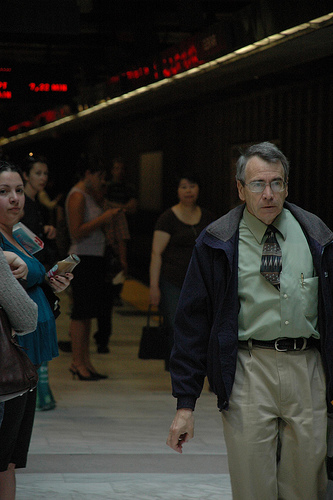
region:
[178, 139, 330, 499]
Man wearing a green button down shirt with a colorful tie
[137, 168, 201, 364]
Woman with black hair walking and carrying a black purse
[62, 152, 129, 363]
Woman standing still and looking at her cell phone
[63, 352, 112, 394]
Black high heel shoes being worn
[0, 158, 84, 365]
Woman wearing a blue shirt holding a bottle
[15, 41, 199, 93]
Red lights in the sky line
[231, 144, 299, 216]
Man with gray hair and wearing glasses without rims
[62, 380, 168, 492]
Light colored stone floor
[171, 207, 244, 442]
Blue jacket with gray pads at the top for warmth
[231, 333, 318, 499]
Khaki pants being worn with a black belt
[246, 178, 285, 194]
Eyeglasses in the photo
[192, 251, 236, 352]
A blue jacket in the photo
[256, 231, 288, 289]
A tie in the photo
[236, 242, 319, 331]
A light green shirt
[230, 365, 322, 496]
A gray trouser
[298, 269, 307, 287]
A pen in the pocket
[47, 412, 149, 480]
A paved floor in the photo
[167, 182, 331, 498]
A man in the photo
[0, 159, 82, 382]
A woman holding a bottle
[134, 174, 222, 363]
A woman with a black hand bag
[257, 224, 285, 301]
tie on a man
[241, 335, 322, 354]
belt on a man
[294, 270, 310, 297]
pen in the mans pocket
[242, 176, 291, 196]
glasses on the man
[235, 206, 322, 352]
green shirt on the man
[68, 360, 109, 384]
a woman's black shoes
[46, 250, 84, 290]
a woman holding a drink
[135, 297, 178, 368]
a woman holding a black purse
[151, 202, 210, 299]
black shirt on the woman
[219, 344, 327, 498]
tan pants on the man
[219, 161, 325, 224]
a man wearing glasses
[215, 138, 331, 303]
a man wearing a tie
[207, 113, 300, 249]
a man with grey hair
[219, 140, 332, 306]
a man with a pen in his shirt pocket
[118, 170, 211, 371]
a woman holding a purse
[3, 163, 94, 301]
a woman holding a bottle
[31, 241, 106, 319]
a glass bottle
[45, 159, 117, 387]
a woman wearing black heels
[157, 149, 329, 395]
a man wearing a blue jacket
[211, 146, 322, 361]
a man wearing a black belt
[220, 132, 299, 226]
The man is wearing glasses.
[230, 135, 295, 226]
The man has hair.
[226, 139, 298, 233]
The man's hair is graying.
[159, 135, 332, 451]
The man is wearing a jacket.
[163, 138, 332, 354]
The man is wearing a tie.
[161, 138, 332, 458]
The man is wearing a shirt.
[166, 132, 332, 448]
The man's shirt is green.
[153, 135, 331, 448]
The man's shirt has a chest pocket.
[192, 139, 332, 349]
The man has a pen in his shirt pocket.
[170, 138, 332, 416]
The man is wearing a belt.